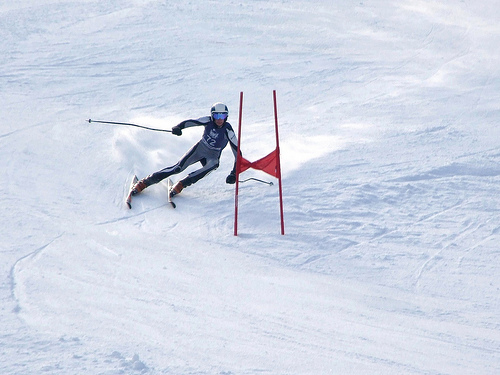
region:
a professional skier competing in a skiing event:
[83, 90, 243, 209]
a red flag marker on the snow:
[232, 88, 284, 237]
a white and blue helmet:
[210, 101, 230, 112]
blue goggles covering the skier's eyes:
[212, 111, 227, 120]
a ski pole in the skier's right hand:
[84, 117, 183, 136]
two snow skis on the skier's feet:
[124, 173, 177, 214]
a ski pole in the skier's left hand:
[225, 175, 275, 187]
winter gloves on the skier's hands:
[172, 125, 236, 184]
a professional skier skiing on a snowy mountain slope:
[84, 102, 243, 212]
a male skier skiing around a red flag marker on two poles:
[80, 88, 285, 238]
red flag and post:
[234, 129, 291, 196]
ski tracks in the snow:
[314, 192, 469, 312]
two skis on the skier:
[108, 173, 175, 223]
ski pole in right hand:
[77, 112, 187, 146]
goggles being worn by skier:
[212, 110, 229, 125]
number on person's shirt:
[201, 123, 220, 165]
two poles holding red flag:
[219, 104, 311, 261]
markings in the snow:
[1, 203, 164, 335]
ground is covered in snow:
[1, 118, 498, 368]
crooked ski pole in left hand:
[231, 174, 276, 197]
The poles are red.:
[230, 92, 290, 252]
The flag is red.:
[237, 143, 281, 182]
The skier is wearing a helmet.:
[207, 98, 237, 129]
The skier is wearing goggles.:
[206, 106, 238, 131]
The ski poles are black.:
[91, 118, 285, 217]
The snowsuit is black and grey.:
[156, 109, 236, 204]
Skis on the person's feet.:
[117, 161, 195, 216]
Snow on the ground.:
[73, 250, 443, 372]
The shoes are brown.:
[127, 178, 194, 204]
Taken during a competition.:
[4, 0, 499, 355]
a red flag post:
[231, 62, 331, 248]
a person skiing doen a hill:
[102, 93, 234, 240]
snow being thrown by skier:
[87, 93, 223, 190]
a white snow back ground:
[74, 20, 222, 95]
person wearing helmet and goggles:
[202, 97, 234, 133]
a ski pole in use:
[77, 113, 183, 140]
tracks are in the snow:
[310, 141, 435, 286]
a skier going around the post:
[65, 75, 378, 287]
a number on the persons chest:
[207, 125, 220, 150]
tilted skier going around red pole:
[78, 80, 317, 243]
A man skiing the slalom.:
[70, 80, 301, 239]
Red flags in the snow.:
[237, 80, 292, 245]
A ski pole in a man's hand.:
[85, 113, 181, 140]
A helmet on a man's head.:
[210, 97, 233, 129]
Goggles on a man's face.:
[207, 108, 234, 120]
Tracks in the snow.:
[293, 81, 444, 186]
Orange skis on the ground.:
[122, 170, 189, 215]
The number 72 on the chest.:
[203, 134, 218, 149]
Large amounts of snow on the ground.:
[328, 51, 444, 221]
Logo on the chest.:
[207, 128, 219, 141]